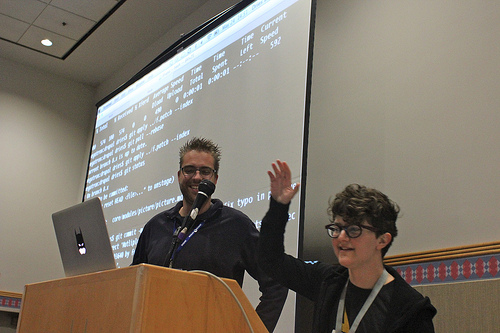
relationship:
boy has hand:
[256, 160, 439, 333] [260, 159, 300, 208]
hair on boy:
[327, 178, 394, 228] [249, 157, 443, 331]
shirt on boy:
[131, 201, 294, 331] [249, 157, 443, 331]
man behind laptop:
[129, 137, 289, 332] [50, 196, 118, 277]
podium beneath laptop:
[11, 264, 268, 331] [50, 196, 118, 277]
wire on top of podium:
[228, 287, 253, 327] [129, 264, 206, 329]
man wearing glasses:
[129, 137, 289, 332] [180, 164, 217, 179]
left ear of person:
[377, 227, 393, 250] [257, 156, 441, 331]